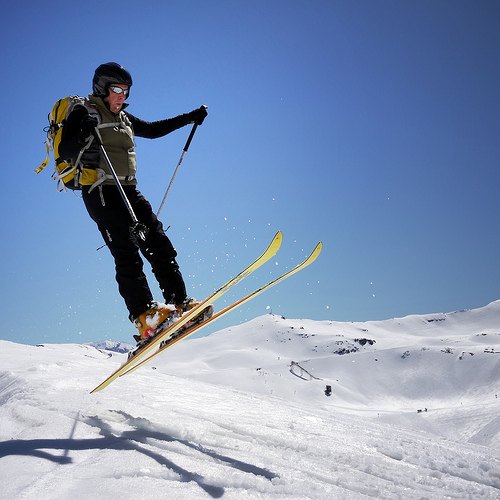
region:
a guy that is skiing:
[21, 48, 323, 406]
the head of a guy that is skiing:
[78, 36, 133, 103]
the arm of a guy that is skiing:
[55, 99, 113, 164]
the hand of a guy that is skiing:
[182, 92, 219, 129]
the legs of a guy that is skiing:
[72, 178, 194, 310]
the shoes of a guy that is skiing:
[128, 289, 206, 341]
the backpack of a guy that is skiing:
[41, 76, 101, 207]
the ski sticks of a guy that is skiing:
[71, 119, 189, 253]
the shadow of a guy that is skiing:
[31, 368, 249, 485]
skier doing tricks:
[32, 38, 313, 402]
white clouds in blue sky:
[321, 73, 396, 135]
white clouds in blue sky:
[352, 108, 444, 180]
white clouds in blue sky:
[271, 76, 358, 148]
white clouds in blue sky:
[330, 175, 454, 227]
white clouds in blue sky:
[277, 19, 358, 67]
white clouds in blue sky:
[350, 85, 457, 153]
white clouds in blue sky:
[194, 25, 284, 89]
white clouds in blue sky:
[335, 108, 410, 156]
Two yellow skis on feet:
[86, 231, 323, 396]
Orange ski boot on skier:
[128, 304, 176, 331]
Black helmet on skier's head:
[90, 62, 132, 89]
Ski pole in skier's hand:
[160, 101, 196, 220]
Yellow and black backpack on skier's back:
[42, 95, 97, 183]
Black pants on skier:
[80, 183, 185, 306]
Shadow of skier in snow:
[0, 429, 296, 481]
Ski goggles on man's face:
[110, 85, 128, 95]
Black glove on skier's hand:
[190, 108, 215, 123]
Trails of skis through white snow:
[215, 408, 460, 488]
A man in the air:
[31, 37, 336, 487]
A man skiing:
[39, 55, 324, 397]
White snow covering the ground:
[2, 295, 497, 498]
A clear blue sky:
[0, 1, 499, 344]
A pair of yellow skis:
[91, 233, 323, 410]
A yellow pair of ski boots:
[123, 285, 215, 340]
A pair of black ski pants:
[85, 189, 189, 314]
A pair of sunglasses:
[109, 85, 131, 98]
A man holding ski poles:
[61, 50, 226, 335]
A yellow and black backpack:
[46, 82, 103, 193]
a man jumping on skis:
[43, 68, 327, 415]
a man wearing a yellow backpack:
[52, 57, 242, 319]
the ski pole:
[84, 124, 151, 244]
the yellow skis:
[98, 230, 310, 404]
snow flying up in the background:
[193, 232, 240, 263]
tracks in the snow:
[253, 402, 455, 499]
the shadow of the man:
[20, 418, 226, 498]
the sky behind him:
[300, 182, 489, 342]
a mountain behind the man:
[218, 318, 488, 410]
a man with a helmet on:
[64, 59, 264, 351]